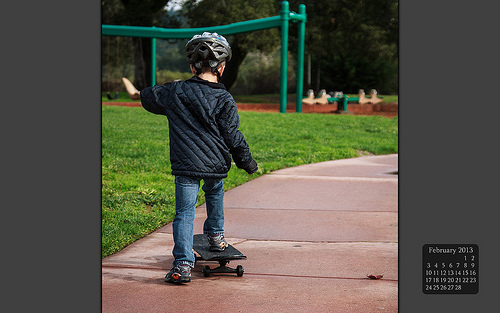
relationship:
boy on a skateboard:
[112, 25, 267, 246] [184, 231, 256, 283]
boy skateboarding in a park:
[121, 31, 263, 284] [100, 1, 397, 309]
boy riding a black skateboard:
[121, 31, 263, 284] [192, 233, 247, 277]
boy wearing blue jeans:
[121, 31, 263, 284] [166, 172, 227, 268]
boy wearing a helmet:
[121, 31, 263, 284] [180, 29, 231, 76]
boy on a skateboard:
[121, 31, 263, 284] [193, 230, 245, 279]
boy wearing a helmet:
[121, 31, 263, 284] [183, 25, 233, 77]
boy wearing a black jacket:
[121, 31, 263, 284] [139, 76, 259, 179]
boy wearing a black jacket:
[121, 31, 263, 284] [133, 80, 258, 180]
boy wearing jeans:
[121, 31, 263, 284] [149, 173, 235, 283]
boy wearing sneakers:
[121, 31, 263, 284] [144, 234, 240, 284]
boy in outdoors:
[121, 31, 263, 284] [129, 28, 394, 293]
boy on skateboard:
[121, 31, 263, 284] [177, 230, 254, 272]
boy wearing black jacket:
[121, 31, 263, 284] [139, 76, 259, 179]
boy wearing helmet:
[121, 31, 263, 284] [165, 28, 249, 79]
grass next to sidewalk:
[105, 98, 274, 242] [116, 169, 388, 305]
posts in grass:
[265, 11, 314, 98] [117, 84, 366, 222]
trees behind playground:
[133, 15, 349, 64] [107, 52, 383, 112]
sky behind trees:
[156, 1, 194, 14] [113, 18, 362, 82]